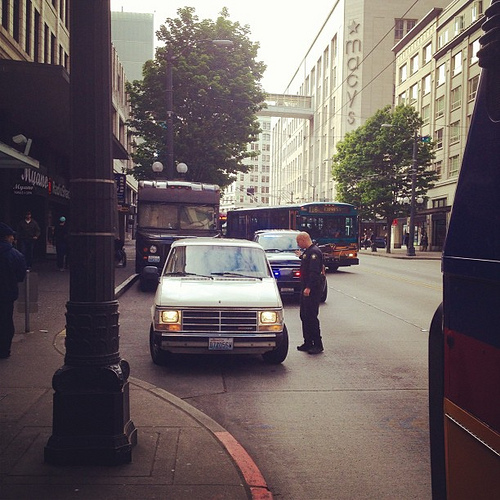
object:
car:
[149, 235, 288, 364]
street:
[117, 245, 449, 496]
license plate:
[206, 333, 236, 355]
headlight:
[157, 306, 182, 327]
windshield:
[164, 243, 269, 281]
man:
[293, 232, 328, 356]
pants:
[297, 288, 324, 348]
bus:
[225, 202, 363, 274]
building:
[383, 2, 497, 247]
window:
[398, 59, 410, 85]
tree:
[354, 102, 433, 256]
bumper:
[148, 329, 287, 358]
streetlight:
[150, 159, 164, 174]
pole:
[163, 42, 176, 179]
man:
[50, 213, 73, 272]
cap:
[57, 214, 65, 222]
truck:
[130, 178, 222, 290]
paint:
[208, 423, 268, 487]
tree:
[331, 121, 380, 250]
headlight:
[148, 243, 160, 253]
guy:
[0, 222, 28, 360]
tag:
[145, 253, 160, 271]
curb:
[213, 431, 274, 499]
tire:
[140, 266, 152, 293]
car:
[247, 228, 327, 305]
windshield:
[140, 197, 218, 235]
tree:
[126, 4, 264, 197]